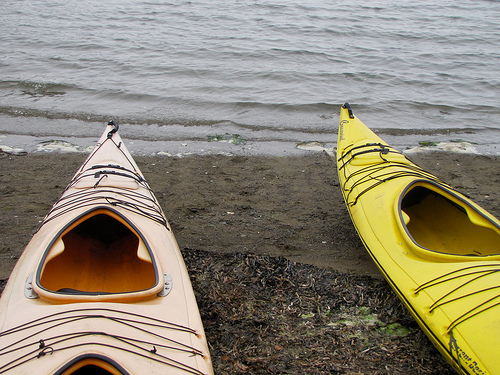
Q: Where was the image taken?
A: It was taken at the shore.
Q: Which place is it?
A: It is a shore.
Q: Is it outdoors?
A: Yes, it is outdoors.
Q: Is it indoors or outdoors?
A: It is outdoors.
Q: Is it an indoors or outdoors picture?
A: It is outdoors.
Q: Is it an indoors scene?
A: No, it is outdoors.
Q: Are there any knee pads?
A: No, there are no knee pads.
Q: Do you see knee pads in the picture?
A: No, there are no knee pads.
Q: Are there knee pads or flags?
A: No, there are no knee pads or flags.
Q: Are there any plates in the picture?
A: Yes, there is a plate.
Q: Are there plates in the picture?
A: Yes, there is a plate.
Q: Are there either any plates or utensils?
A: Yes, there is a plate.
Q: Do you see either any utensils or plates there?
A: Yes, there is a plate.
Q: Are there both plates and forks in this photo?
A: No, there is a plate but no forks.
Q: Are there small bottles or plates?
A: Yes, there is a small plate.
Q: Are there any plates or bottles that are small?
A: Yes, the plate is small.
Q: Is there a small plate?
A: Yes, there is a small plate.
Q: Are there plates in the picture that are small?
A: Yes, there is a plate that is small.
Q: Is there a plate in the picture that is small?
A: Yes, there is a plate that is small.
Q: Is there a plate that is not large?
A: Yes, there is a small plate.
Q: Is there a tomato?
A: No, there are no tomatoes.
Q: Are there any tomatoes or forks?
A: No, there are no tomatoes or forks.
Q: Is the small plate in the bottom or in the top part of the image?
A: The plate is in the bottom of the image.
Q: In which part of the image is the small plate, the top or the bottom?
A: The plate is in the bottom of the image.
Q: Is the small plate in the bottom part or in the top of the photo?
A: The plate is in the bottom of the image.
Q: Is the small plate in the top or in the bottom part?
A: The plate is in the bottom of the image.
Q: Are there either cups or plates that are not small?
A: No, there is a plate but it is small.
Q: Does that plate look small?
A: Yes, the plate is small.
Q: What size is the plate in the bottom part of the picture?
A: The plate is small.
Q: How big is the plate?
A: The plate is small.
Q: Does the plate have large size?
A: No, the plate is small.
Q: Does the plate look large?
A: No, the plate is small.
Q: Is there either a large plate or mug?
A: No, there is a plate but it is small.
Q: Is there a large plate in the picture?
A: No, there is a plate but it is small.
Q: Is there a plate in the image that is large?
A: No, there is a plate but it is small.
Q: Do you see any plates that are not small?
A: No, there is a plate but it is small.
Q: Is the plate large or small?
A: The plate is small.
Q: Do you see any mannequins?
A: No, there are no mannequins.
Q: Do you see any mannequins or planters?
A: No, there are no mannequins or planters.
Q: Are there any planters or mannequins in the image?
A: No, there are no mannequins or planters.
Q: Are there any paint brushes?
A: No, there are no paint brushes.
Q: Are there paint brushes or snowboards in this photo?
A: No, there are no paint brushes or snowboards.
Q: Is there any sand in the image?
A: Yes, there is sand.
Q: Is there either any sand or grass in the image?
A: Yes, there is sand.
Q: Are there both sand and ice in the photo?
A: No, there is sand but no ice.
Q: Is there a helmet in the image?
A: No, there are no helmets.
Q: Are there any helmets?
A: No, there are no helmets.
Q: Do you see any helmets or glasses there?
A: No, there are no helmets or glasses.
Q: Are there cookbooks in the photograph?
A: No, there are no cookbooks.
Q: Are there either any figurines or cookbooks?
A: No, there are no cookbooks or figurines.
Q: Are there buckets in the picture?
A: No, there are no buckets.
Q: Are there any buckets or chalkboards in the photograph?
A: No, there are no buckets or chalkboards.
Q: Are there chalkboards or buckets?
A: No, there are no buckets or chalkboards.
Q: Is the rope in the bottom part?
A: Yes, the rope is in the bottom of the image.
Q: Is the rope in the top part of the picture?
A: No, the rope is in the bottom of the image.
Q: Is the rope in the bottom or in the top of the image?
A: The rope is in the bottom of the image.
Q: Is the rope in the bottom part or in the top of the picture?
A: The rope is in the bottom of the image.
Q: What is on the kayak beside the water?
A: The rope is on the canoe.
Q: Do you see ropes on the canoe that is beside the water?
A: Yes, there is a rope on the canoe.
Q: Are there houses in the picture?
A: No, there are no houses.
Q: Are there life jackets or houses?
A: No, there are no houses or life jackets.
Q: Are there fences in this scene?
A: No, there are no fences.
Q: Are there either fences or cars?
A: No, there are no fences or cars.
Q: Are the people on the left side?
A: Yes, the people are on the left of the image.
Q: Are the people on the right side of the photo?
A: No, the people are on the left of the image.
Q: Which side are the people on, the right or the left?
A: The people are on the left of the image.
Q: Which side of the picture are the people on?
A: The people are on the left of the image.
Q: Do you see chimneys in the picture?
A: No, there are no chimneys.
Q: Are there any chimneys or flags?
A: No, there are no chimneys or flags.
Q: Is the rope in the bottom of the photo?
A: Yes, the rope is in the bottom of the image.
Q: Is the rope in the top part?
A: No, the rope is in the bottom of the image.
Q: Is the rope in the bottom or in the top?
A: The rope is in the bottom of the image.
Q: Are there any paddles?
A: No, there are no paddles.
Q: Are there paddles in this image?
A: No, there are no paddles.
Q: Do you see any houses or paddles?
A: No, there are no paddles or houses.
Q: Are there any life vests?
A: No, there are no life vests.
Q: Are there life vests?
A: No, there are no life vests.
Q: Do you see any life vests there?
A: No, there are no life vests.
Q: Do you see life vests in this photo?
A: No, there are no life vests.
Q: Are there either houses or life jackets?
A: No, there are no life jackets or houses.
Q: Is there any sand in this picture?
A: Yes, there is sand.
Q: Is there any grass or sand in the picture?
A: Yes, there is sand.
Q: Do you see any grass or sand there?
A: Yes, there is sand.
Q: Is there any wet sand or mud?
A: Yes, there is wet sand.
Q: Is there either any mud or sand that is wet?
A: Yes, the sand is wet.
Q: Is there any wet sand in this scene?
A: Yes, there is wet sand.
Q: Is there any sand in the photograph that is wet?
A: Yes, there is sand that is wet.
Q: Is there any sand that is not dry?
A: Yes, there is wet sand.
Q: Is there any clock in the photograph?
A: No, there are no clocks.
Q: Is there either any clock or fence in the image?
A: No, there are no clocks or fences.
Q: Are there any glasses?
A: No, there are no glasses.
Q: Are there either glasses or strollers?
A: No, there are no glasses or strollers.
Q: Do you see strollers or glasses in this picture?
A: No, there are no glasses or strollers.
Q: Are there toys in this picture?
A: No, there are no toys.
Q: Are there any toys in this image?
A: No, there are no toys.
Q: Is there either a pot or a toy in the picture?
A: No, there are no toys or pots.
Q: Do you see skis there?
A: No, there are no skis.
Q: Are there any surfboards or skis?
A: No, there are no skis or surfboards.